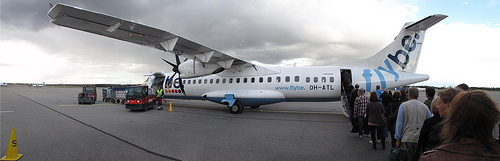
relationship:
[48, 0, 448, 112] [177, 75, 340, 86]
plane has windows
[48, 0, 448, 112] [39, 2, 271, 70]
plane has wings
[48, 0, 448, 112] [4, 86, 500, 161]
plane on tarmac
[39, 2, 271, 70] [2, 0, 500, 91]
clouds in sky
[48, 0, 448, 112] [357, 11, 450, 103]
plane has tail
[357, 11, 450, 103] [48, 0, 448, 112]
letters on plane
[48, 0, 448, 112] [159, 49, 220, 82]
plane has engine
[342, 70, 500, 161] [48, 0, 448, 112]
people boarding plane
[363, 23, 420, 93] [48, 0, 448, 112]
words on plane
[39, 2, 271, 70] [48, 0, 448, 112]
wings on plane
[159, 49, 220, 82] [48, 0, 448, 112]
engine on plane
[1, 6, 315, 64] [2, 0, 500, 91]
clouds in sky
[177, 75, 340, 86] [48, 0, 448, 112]
windows on plane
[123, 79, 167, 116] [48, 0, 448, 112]
truck near plane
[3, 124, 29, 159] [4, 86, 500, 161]
cone on tarmac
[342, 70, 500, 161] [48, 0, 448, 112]
people waiting to board plane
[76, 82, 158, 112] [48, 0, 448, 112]
vehicles to left of plane